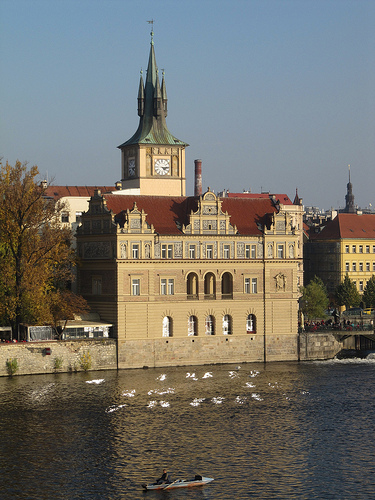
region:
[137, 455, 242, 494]
Man in boat in water.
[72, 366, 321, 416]
Several white objects in water near large building.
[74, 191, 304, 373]
Large brick building with arched openings near water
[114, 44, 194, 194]
Clock tower with green roof.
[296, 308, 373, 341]
Group of people sitting outside near water.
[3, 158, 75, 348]
Large tree near big building.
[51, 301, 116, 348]
Building resembling a greenhouse attached to building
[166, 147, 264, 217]
Large building with tall red chimney.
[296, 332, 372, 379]
Turbulent water near bridge.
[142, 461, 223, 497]
Man in boat has paddles.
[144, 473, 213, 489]
a person rowing a boat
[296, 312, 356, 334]
people along the shore and on the bridge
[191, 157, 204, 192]
a smoke stack above the buildings